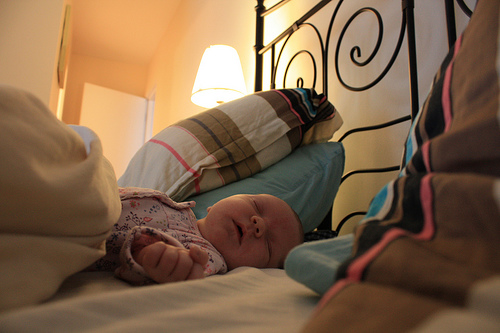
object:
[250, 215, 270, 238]
nose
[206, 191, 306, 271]
face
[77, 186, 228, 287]
body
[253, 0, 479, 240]
black railings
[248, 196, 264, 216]
eye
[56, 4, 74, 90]
picture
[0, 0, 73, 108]
wall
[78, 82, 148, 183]
door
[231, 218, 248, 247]
mouth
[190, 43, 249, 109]
lamp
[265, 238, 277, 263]
eye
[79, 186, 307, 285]
baby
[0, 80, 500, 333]
bed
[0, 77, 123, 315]
blanket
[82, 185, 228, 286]
outfit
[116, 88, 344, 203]
pillow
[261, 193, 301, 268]
forehead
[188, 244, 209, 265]
thumb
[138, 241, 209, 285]
hand